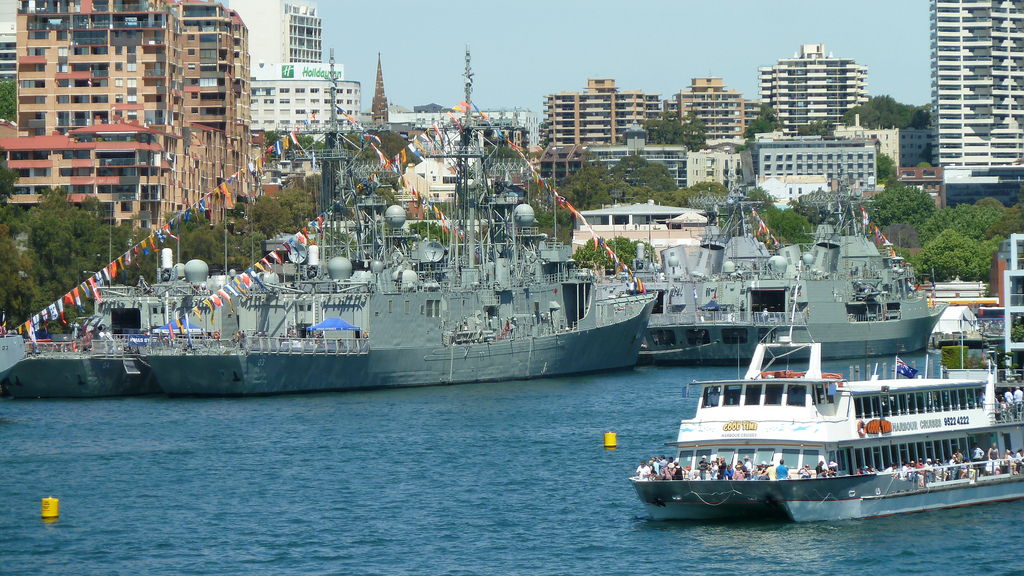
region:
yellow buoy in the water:
[30, 473, 81, 532]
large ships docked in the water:
[118, 101, 621, 399]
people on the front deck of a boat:
[650, 451, 796, 496]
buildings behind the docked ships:
[498, 70, 863, 245]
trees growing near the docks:
[15, 181, 155, 340]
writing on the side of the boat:
[893, 414, 983, 431]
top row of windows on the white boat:
[852, 388, 986, 414]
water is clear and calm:
[103, 427, 451, 557]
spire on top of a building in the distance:
[362, 37, 398, 118]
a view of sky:
[442, 42, 575, 113]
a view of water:
[401, 448, 538, 559]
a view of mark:
[593, 421, 673, 491]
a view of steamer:
[596, 296, 1012, 573]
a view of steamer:
[129, 143, 604, 420]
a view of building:
[101, 50, 1015, 279]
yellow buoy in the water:
[596, 417, 626, 457]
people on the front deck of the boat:
[619, 446, 842, 492]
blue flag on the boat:
[884, 353, 923, 388]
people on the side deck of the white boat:
[878, 445, 1018, 509]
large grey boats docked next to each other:
[11, 234, 670, 381]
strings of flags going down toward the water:
[34, 152, 398, 399]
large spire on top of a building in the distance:
[352, 31, 392, 139]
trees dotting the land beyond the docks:
[551, 135, 954, 292]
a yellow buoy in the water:
[4, 479, 132, 538]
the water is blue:
[184, 390, 590, 553]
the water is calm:
[153, 406, 540, 547]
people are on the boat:
[620, 405, 966, 554]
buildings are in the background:
[39, 11, 922, 190]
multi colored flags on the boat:
[184, 100, 510, 325]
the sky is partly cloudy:
[373, 10, 800, 90]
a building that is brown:
[17, 2, 230, 203]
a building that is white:
[257, 16, 356, 135]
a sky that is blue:
[509, 7, 661, 80]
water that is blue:
[242, 426, 502, 572]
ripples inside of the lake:
[336, 490, 412, 536]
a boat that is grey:
[175, 224, 692, 358]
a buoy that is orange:
[23, 478, 75, 548]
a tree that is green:
[889, 189, 1008, 276]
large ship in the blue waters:
[592, 304, 1020, 527]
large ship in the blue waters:
[5, 57, 660, 386]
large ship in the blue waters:
[593, 147, 925, 367]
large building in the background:
[931, 2, 1012, 177]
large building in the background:
[751, 46, 873, 148]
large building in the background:
[656, 74, 755, 144]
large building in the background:
[526, 78, 653, 148]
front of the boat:
[562, 345, 904, 541]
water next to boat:
[394, 456, 562, 523]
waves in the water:
[305, 424, 552, 561]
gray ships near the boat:
[47, 113, 853, 430]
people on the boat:
[578, 402, 867, 523]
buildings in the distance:
[498, 4, 916, 169]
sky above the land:
[509, 2, 678, 64]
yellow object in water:
[0, 459, 127, 559]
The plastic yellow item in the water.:
[40, 496, 66, 520]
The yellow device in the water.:
[591, 410, 621, 459]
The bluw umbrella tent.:
[306, 309, 368, 355]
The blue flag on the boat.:
[885, 351, 914, 383]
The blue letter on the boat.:
[942, 415, 975, 432]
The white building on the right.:
[928, 7, 1018, 194]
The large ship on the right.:
[634, 192, 930, 355]